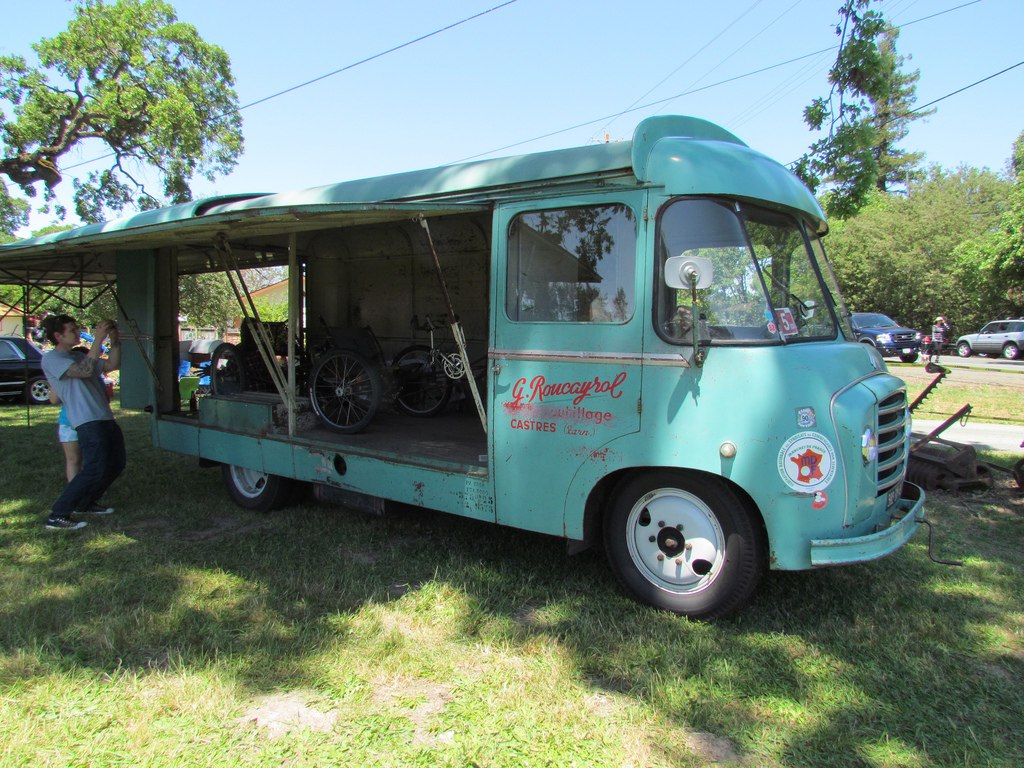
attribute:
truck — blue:
[0, 116, 927, 628]